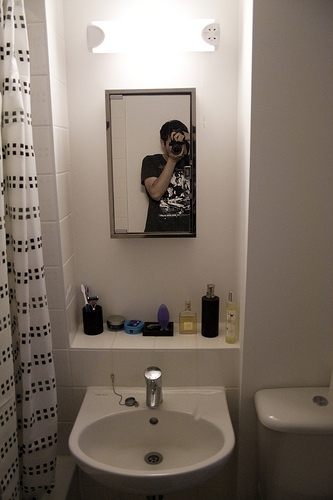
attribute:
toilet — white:
[246, 377, 331, 498]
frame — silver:
[103, 87, 201, 244]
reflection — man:
[134, 110, 188, 230]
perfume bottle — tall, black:
[198, 279, 219, 342]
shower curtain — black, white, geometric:
[1, 0, 65, 498]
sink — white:
[66, 364, 242, 492]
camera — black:
[166, 133, 190, 158]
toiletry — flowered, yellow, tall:
[220, 287, 243, 350]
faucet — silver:
[136, 359, 169, 410]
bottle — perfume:
[175, 300, 199, 341]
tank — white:
[248, 382, 331, 491]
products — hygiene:
[143, 281, 241, 350]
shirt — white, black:
[139, 154, 192, 231]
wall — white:
[27, 7, 325, 391]